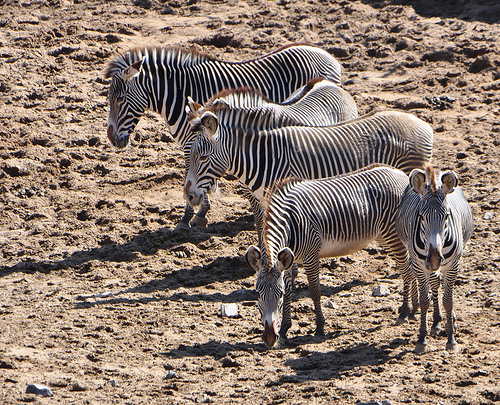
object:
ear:
[244, 244, 262, 273]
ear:
[409, 169, 428, 195]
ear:
[277, 247, 295, 271]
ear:
[441, 170, 458, 194]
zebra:
[183, 105, 434, 264]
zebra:
[243, 162, 421, 348]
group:
[102, 36, 474, 354]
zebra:
[100, 43, 343, 230]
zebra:
[186, 75, 359, 251]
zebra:
[394, 163, 475, 355]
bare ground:
[1, 2, 499, 403]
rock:
[220, 302, 239, 318]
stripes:
[156, 50, 166, 114]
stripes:
[262, 129, 274, 201]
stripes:
[415, 210, 424, 249]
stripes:
[317, 178, 348, 244]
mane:
[104, 44, 213, 80]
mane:
[260, 176, 303, 269]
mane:
[427, 166, 438, 194]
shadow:
[0, 212, 256, 280]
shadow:
[260, 334, 408, 387]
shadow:
[164, 331, 343, 362]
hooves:
[174, 218, 190, 227]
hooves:
[415, 343, 428, 355]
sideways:
[0, 0, 224, 405]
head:
[103, 49, 152, 150]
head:
[182, 111, 228, 207]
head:
[253, 265, 292, 349]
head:
[409, 168, 458, 272]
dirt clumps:
[77, 208, 93, 220]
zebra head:
[245, 245, 297, 348]